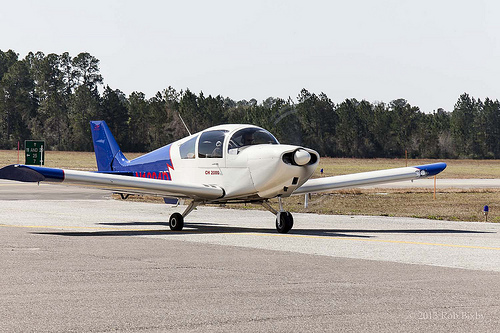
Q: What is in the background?
A: Green trees.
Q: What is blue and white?
A: The plane.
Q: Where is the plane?
A: On the ground.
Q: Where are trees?
A: In the distance.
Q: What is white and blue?
A: Small plane.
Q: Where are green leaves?
A: On trees.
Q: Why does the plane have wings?
A: To be able to fly.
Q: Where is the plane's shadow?
A: On the ground.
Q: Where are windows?
A: On the plane.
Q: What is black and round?
A: Plane's wheels.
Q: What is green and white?
A: A sign.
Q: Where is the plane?
A: On the runway.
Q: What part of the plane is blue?
A: The back part.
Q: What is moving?
A: The propeller.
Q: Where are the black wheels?
A: On the plane.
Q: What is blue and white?
A: A small aircraft.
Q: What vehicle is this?
A: A airplane.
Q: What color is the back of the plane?
A: Blue.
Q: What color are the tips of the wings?
A: Blue.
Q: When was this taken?
A: Daytime.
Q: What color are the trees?
A: Green.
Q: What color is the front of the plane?
A: White.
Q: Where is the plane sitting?
A: On the runway.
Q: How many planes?
A: 1.